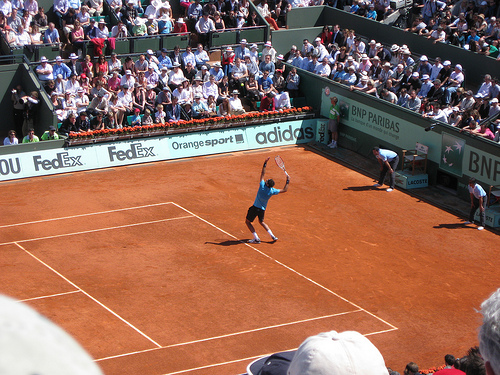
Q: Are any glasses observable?
A: No, there are no glasses.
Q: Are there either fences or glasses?
A: No, there are no glasses or fences.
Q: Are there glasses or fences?
A: No, there are no glasses or fences.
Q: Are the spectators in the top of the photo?
A: Yes, the spectators are in the top of the image.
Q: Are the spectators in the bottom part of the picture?
A: No, the spectators are in the top of the image.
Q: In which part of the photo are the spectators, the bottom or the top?
A: The spectators are in the top of the image.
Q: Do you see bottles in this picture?
A: No, there are no bottles.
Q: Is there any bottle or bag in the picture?
A: No, there are no bottles or bags.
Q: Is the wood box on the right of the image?
A: Yes, the box is on the right of the image.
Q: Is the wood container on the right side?
A: Yes, the box is on the right of the image.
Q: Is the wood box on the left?
A: No, the box is on the right of the image.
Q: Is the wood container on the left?
A: No, the box is on the right of the image.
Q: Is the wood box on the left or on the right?
A: The box is on the right of the image.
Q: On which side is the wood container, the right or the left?
A: The box is on the right of the image.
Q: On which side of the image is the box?
A: The box is on the right of the image.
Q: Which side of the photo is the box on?
A: The box is on the right of the image.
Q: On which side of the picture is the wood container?
A: The box is on the right of the image.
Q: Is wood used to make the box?
A: Yes, the box is made of wood.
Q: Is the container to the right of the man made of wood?
A: Yes, the box is made of wood.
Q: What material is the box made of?
A: The box is made of wood.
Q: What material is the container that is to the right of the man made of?
A: The box is made of wood.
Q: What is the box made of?
A: The box is made of wood.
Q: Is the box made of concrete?
A: No, the box is made of wood.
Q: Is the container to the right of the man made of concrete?
A: No, the box is made of wood.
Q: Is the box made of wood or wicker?
A: The box is made of wood.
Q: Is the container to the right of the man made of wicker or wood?
A: The box is made of wood.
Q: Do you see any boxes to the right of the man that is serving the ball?
A: Yes, there is a box to the right of the man.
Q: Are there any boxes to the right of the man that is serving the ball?
A: Yes, there is a box to the right of the man.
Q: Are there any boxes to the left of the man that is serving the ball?
A: No, the box is to the right of the man.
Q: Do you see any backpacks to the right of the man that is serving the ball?
A: No, there is a box to the right of the man.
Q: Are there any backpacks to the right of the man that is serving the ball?
A: No, there is a box to the right of the man.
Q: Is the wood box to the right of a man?
A: Yes, the box is to the right of a man.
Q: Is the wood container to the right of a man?
A: Yes, the box is to the right of a man.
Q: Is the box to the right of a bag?
A: No, the box is to the right of a man.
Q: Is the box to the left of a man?
A: No, the box is to the right of a man.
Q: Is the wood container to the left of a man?
A: No, the box is to the right of a man.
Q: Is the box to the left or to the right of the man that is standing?
A: The box is to the right of the man.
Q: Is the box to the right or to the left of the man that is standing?
A: The box is to the right of the man.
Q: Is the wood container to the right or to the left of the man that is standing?
A: The box is to the right of the man.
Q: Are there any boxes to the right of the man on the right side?
A: Yes, there is a box to the right of the man.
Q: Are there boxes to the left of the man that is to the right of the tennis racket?
A: No, the box is to the right of the man.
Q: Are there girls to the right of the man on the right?
A: No, there is a box to the right of the man.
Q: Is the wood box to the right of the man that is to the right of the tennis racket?
A: Yes, the box is to the right of the man.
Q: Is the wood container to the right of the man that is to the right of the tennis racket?
A: Yes, the box is to the right of the man.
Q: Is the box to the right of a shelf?
A: No, the box is to the right of the man.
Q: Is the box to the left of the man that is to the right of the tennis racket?
A: No, the box is to the right of the man.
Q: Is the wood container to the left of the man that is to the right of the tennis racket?
A: No, the box is to the right of the man.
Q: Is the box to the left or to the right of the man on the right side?
A: The box is to the right of the man.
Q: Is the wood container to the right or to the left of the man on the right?
A: The box is to the right of the man.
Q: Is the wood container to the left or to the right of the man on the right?
A: The box is to the right of the man.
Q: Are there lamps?
A: No, there are no lamps.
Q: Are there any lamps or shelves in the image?
A: No, there are no lamps or shelves.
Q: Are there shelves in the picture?
A: No, there are no shelves.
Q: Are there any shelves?
A: No, there are no shelves.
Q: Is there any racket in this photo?
A: Yes, there is a racket.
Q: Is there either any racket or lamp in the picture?
A: Yes, there is a racket.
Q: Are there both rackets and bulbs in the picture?
A: No, there is a racket but no light bulbs.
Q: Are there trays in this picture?
A: No, there are no trays.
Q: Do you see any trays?
A: No, there are no trays.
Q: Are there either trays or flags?
A: No, there are no trays or flags.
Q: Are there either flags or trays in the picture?
A: No, there are no trays or flags.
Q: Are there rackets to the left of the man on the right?
A: Yes, there is a racket to the left of the man.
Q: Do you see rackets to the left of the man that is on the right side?
A: Yes, there is a racket to the left of the man.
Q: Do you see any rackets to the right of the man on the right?
A: No, the racket is to the left of the man.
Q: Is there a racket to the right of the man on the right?
A: No, the racket is to the left of the man.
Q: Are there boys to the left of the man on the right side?
A: No, there is a racket to the left of the man.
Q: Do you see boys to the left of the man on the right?
A: No, there is a racket to the left of the man.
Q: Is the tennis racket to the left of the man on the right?
A: Yes, the tennis racket is to the left of the man.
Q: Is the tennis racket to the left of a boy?
A: No, the tennis racket is to the left of the man.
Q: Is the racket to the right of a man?
A: No, the racket is to the left of a man.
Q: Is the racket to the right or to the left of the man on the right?
A: The racket is to the left of the man.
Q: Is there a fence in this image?
A: No, there are no fences.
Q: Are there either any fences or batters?
A: No, there are no fences or batters.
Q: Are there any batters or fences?
A: No, there are no fences or batters.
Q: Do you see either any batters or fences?
A: No, there are no fences or batters.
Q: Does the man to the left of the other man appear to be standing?
A: Yes, the man is standing.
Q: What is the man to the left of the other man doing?
A: The man is standing.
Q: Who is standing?
A: The man is standing.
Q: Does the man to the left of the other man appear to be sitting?
A: No, the man is standing.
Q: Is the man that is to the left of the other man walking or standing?
A: The man is standing.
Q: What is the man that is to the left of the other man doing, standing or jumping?
A: The man is standing.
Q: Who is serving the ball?
A: The man is serving the ball.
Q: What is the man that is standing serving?
A: The man is serving the ball.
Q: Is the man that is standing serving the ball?
A: Yes, the man is serving the ball.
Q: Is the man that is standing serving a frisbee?
A: No, the man is serving the ball.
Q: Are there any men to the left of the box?
A: Yes, there is a man to the left of the box.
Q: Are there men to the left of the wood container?
A: Yes, there is a man to the left of the box.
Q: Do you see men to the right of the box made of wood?
A: No, the man is to the left of the box.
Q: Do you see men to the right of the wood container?
A: No, the man is to the left of the box.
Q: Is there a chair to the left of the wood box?
A: No, there is a man to the left of the box.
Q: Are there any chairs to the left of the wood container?
A: No, there is a man to the left of the box.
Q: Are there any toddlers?
A: No, there are no toddlers.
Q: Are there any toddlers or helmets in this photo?
A: No, there are no toddlers or helmets.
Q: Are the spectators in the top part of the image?
A: Yes, the spectators are in the top of the image.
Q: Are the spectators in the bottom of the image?
A: No, the spectators are in the top of the image.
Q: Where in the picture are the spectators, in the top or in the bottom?
A: The spectators are in the top of the image.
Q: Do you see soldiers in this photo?
A: No, there are no soldiers.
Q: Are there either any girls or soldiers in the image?
A: No, there are no soldiers or girls.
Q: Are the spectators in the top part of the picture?
A: Yes, the spectators are in the top of the image.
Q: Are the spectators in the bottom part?
A: No, the spectators are in the top of the image.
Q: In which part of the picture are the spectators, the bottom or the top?
A: The spectators are in the top of the image.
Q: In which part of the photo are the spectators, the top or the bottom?
A: The spectators are in the top of the image.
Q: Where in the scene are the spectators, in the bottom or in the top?
A: The spectators are in the top of the image.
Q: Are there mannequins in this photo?
A: No, there are no mannequins.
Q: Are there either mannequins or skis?
A: No, there are no mannequins or skis.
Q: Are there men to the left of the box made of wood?
A: Yes, there is a man to the left of the box.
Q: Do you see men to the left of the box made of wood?
A: Yes, there is a man to the left of the box.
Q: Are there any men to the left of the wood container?
A: Yes, there is a man to the left of the box.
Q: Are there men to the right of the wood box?
A: No, the man is to the left of the box.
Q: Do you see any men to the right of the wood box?
A: No, the man is to the left of the box.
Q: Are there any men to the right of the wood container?
A: No, the man is to the left of the box.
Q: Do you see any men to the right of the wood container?
A: No, the man is to the left of the box.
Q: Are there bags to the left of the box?
A: No, there is a man to the left of the box.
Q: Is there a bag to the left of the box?
A: No, there is a man to the left of the box.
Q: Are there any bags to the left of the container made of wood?
A: No, there is a man to the left of the box.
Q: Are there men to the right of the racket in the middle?
A: Yes, there is a man to the right of the racket.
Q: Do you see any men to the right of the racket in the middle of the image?
A: Yes, there is a man to the right of the racket.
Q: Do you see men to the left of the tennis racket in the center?
A: No, the man is to the right of the tennis racket.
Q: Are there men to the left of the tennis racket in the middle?
A: No, the man is to the right of the tennis racket.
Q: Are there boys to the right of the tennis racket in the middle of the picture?
A: No, there is a man to the right of the tennis racket.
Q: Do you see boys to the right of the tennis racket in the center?
A: No, there is a man to the right of the tennis racket.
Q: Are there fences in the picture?
A: No, there are no fences.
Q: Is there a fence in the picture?
A: No, there are no fences.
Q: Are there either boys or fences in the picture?
A: No, there are no fences or boys.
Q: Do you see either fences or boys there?
A: No, there are no fences or boys.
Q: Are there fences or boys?
A: No, there are no fences or boys.